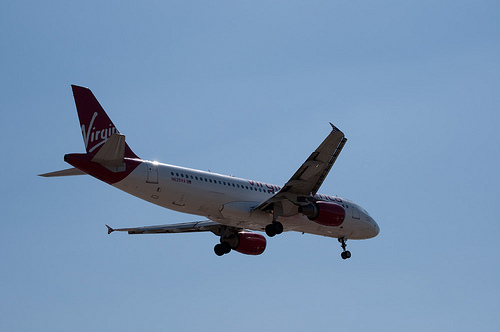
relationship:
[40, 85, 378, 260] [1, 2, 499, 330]
jet in air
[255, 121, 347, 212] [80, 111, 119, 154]
wing has a logo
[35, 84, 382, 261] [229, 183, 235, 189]
jet has a window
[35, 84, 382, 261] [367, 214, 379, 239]
jet has a nose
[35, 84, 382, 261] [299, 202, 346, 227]
jet has an engine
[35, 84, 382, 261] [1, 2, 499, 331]
jet in air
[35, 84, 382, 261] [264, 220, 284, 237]
jet has a wheels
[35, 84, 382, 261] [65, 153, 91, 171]
jet has a tail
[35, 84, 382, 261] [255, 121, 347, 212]
jet has a wing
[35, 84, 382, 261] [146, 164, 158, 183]
jet has a door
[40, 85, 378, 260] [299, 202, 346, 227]
jet has an engine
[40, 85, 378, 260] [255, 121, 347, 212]
jet has a wing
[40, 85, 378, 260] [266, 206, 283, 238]
jet has landing gear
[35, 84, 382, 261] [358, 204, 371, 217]
jet has a cockpit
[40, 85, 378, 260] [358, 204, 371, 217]
jet has a cockpit